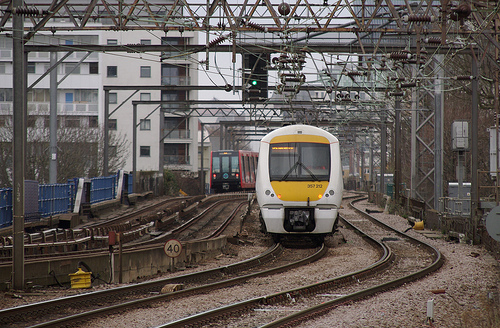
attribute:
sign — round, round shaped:
[164, 239, 184, 259]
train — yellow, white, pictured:
[253, 122, 344, 251]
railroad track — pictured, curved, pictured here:
[1, 193, 443, 323]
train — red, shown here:
[210, 146, 259, 190]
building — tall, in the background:
[1, 8, 199, 176]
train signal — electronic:
[239, 51, 271, 105]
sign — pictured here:
[269, 144, 296, 154]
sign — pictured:
[215, 149, 235, 158]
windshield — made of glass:
[267, 140, 330, 181]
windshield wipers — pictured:
[280, 161, 317, 182]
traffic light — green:
[249, 78, 259, 87]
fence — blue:
[1, 174, 119, 228]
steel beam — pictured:
[430, 51, 449, 231]